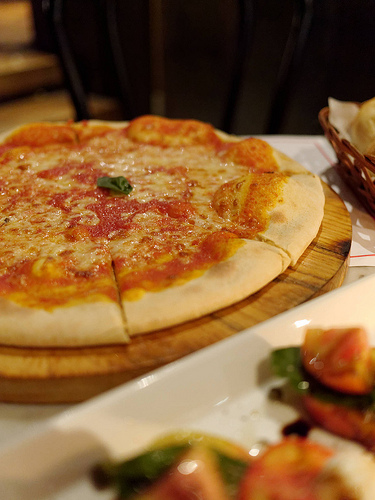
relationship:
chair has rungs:
[29, 0, 325, 121] [75, 7, 317, 97]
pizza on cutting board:
[0, 114, 323, 347] [2, 177, 357, 408]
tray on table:
[0, 115, 353, 404] [0, 133, 374, 458]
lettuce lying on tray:
[87, 440, 251, 498] [2, 271, 372, 496]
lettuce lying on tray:
[271, 344, 374, 412] [2, 271, 372, 496]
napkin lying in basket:
[329, 97, 374, 163] [315, 94, 373, 218]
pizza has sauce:
[0, 114, 323, 347] [75, 172, 166, 239]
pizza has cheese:
[0, 114, 323, 347] [126, 145, 209, 166]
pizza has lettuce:
[0, 114, 326, 348] [97, 173, 142, 194]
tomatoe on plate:
[240, 436, 328, 498] [1, 283, 357, 487]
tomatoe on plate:
[303, 324, 360, 392] [1, 283, 357, 487]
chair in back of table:
[45, 0, 316, 111] [62, 86, 374, 327]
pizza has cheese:
[0, 114, 323, 347] [1, 135, 252, 278]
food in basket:
[326, 89, 373, 163] [315, 94, 373, 218]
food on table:
[16, 138, 372, 452] [2, 138, 362, 404]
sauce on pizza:
[89, 189, 153, 244] [0, 114, 323, 347]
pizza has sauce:
[0, 114, 323, 347] [89, 189, 153, 244]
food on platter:
[256, 316, 373, 388] [94, 269, 369, 387]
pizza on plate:
[0, 114, 323, 347] [1, 177, 352, 403]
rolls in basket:
[344, 96, 374, 157] [314, 100, 374, 215]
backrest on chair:
[93, 4, 315, 106] [48, 6, 349, 162]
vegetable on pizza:
[97, 175, 132, 194] [0, 114, 323, 347]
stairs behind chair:
[11, 15, 147, 129] [61, 6, 283, 138]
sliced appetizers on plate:
[160, 414, 282, 490] [1, 283, 357, 487]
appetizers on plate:
[113, 305, 366, 497] [1, 266, 373, 499]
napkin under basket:
[349, 240, 373, 273] [324, 125, 364, 185]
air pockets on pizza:
[206, 132, 284, 232] [66, 123, 292, 291]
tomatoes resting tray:
[133, 319, 374, 497] [2, 271, 372, 496]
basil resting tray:
[90, 347, 369, 488] [2, 271, 372, 496]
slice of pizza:
[95, 195, 294, 338] [0, 114, 323, 347]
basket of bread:
[317, 104, 373, 200] [346, 95, 374, 155]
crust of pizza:
[4, 281, 300, 372] [1, 247, 248, 345]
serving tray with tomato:
[0, 267, 375, 498] [297, 319, 371, 395]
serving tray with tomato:
[0, 267, 375, 498] [235, 431, 335, 498]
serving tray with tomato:
[0, 267, 375, 498] [136, 437, 230, 498]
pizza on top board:
[0, 114, 323, 347] [10, 100, 346, 444]